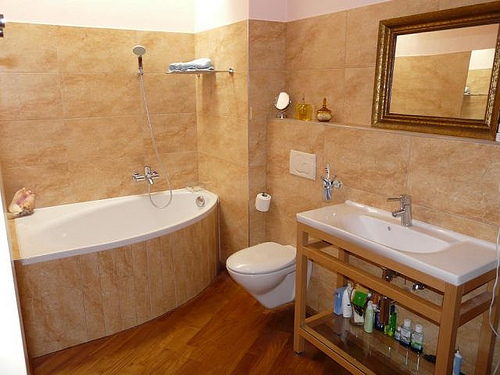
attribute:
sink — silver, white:
[341, 193, 450, 268]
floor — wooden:
[180, 310, 253, 374]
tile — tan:
[167, 258, 205, 289]